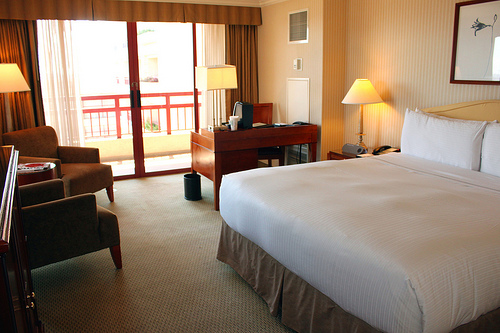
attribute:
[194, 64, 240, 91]
lamp shade — square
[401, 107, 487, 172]
pillow — white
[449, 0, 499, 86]
picture — framed, hanging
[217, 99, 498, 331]
bed — white, large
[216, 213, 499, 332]
bed skirt — tan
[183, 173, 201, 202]
trash can — black, small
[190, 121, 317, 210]
desk — brown, wooden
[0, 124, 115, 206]
chair — brown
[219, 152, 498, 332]
sheet — white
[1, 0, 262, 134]
curtains — hanging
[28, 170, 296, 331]
carpet — tan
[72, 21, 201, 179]
door — glass